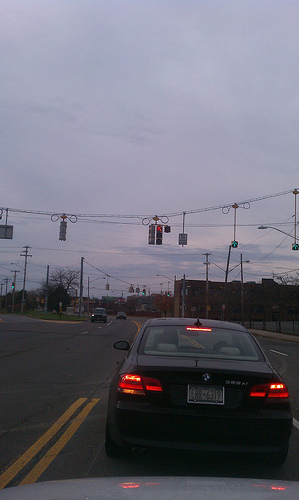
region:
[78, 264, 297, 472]
this is a car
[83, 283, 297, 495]
a car on the street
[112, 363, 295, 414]
back lights of car lit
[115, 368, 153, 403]
this is a break light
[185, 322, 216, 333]
this is an upper break light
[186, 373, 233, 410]
license plate on car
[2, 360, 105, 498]
yellow lines on street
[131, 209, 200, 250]
traffic light hanging up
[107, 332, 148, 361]
side mirror on car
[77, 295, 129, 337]
car driving in opposite direction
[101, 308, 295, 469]
back end of car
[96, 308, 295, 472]
rear end of small black car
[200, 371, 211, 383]
BMW logo on car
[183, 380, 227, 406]
identification tag on car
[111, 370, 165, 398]
red rear tail light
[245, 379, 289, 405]
right rear end light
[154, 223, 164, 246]
three light traffic signal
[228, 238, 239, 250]
lit green arrow on signal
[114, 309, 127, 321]
front end of small car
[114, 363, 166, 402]
light of a car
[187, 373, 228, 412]
plate of a car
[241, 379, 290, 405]
tail of a car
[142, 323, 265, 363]
window of a car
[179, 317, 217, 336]
light of a car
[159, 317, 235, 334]
roof of a car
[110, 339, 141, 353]
mirror of a car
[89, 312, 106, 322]
front of a car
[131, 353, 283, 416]
trunk of a car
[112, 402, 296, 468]
bumper of a car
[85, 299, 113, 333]
this is a car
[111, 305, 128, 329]
this is a car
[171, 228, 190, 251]
this is a sign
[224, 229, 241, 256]
this is a sign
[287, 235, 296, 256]
this is a sign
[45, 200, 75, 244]
this is a sign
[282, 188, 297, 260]
Large traffic signal in the air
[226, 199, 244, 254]
Large traffic signal in the air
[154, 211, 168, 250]
Large traffic signal in the air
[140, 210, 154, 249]
Large traffic signal in the air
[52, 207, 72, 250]
Large traffic signal in the air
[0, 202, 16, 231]
Large traffic signal in the air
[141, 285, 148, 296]
Large traffic signal in the air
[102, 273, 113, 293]
Large traffic signal in the air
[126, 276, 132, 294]
Large traffic signal in the air